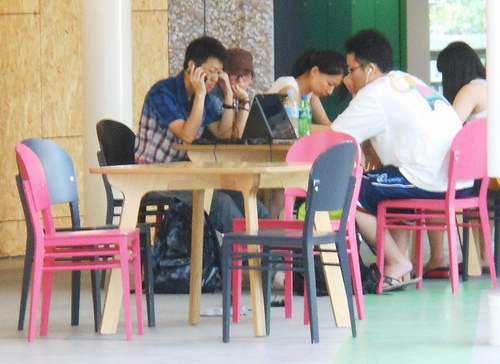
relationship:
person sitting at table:
[325, 29, 475, 292] [175, 142, 330, 293]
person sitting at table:
[132, 35, 235, 284] [175, 142, 330, 293]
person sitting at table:
[436, 40, 497, 280] [175, 142, 330, 293]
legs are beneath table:
[95, 185, 356, 334] [87, 158, 359, 334]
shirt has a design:
[328, 69, 477, 196] [389, 73, 454, 113]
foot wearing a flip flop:
[369, 259, 422, 296] [377, 277, 421, 291]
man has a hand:
[131, 35, 236, 290] [189, 65, 205, 90]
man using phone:
[131, 35, 236, 290] [187, 64, 208, 83]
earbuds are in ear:
[365, 68, 373, 85] [364, 62, 377, 76]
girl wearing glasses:
[221, 45, 266, 187] [226, 69, 253, 82]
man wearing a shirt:
[131, 35, 236, 290] [134, 72, 221, 165]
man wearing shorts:
[325, 29, 474, 294] [351, 166, 477, 217]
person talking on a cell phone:
[132, 35, 235, 284] [184, 58, 208, 85]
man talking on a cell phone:
[131, 35, 236, 290] [184, 58, 208, 85]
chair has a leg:
[219, 141, 358, 343] [99, 208, 114, 291]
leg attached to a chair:
[99, 208, 114, 291] [219, 141, 358, 343]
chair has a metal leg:
[219, 141, 358, 343] [99, 208, 114, 291]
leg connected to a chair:
[99, 208, 114, 291] [219, 141, 358, 343]